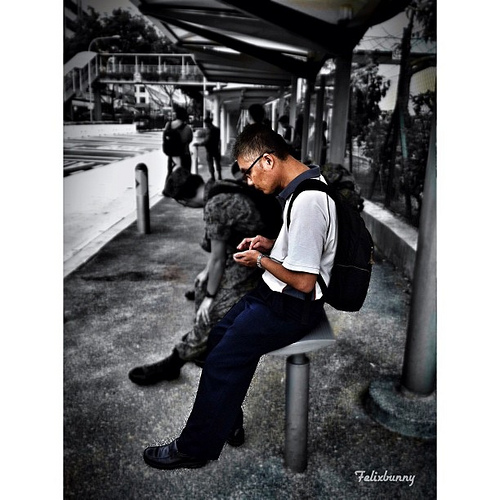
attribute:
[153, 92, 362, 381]
people — several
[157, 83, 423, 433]
man — sitting, looking, typing, wearing, wear, shirt, carrying, colored, dress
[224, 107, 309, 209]
head — person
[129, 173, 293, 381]
soldier — dressed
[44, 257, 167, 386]
grass — covered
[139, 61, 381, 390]
person — background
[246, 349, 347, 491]
pole — metal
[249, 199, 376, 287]
shirt — t, white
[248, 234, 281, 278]
watch — silver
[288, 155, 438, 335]
backpack — black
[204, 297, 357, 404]
bench — silver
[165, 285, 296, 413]
jean — blue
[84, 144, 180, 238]
walkway — above